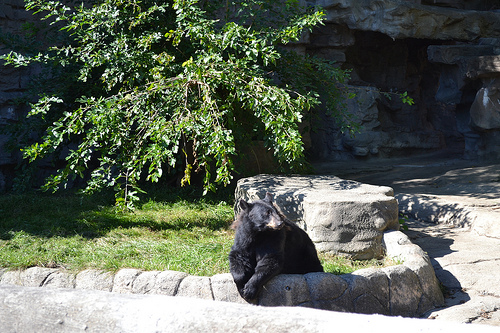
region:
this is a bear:
[226, 190, 312, 287]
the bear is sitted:
[224, 192, 314, 297]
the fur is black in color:
[292, 235, 309, 253]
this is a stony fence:
[375, 240, 425, 305]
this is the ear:
[235, 196, 249, 211]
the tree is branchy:
[116, 32, 308, 151]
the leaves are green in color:
[126, 103, 197, 142]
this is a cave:
[378, 39, 461, 136]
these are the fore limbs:
[221, 256, 278, 293]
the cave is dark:
[366, 50, 431, 91]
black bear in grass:
[232, 192, 320, 298]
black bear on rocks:
[233, 193, 323, 301]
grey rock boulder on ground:
[236, 175, 398, 253]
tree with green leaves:
[7, 0, 322, 205]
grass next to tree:
[6, 192, 234, 275]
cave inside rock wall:
[348, 25, 449, 150]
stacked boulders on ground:
[309, 6, 478, 158]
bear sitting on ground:
[233, 190, 323, 295]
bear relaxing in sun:
[233, 191, 323, 302]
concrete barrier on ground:
[3, 231, 439, 331]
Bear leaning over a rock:
[216, 199, 289, 291]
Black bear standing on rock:
[195, 160, 327, 283]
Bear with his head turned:
[191, 162, 297, 237]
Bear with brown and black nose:
[243, 208, 304, 248]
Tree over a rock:
[54, 45, 276, 192]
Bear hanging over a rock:
[211, 173, 343, 307]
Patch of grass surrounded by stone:
[58, 183, 209, 285]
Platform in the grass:
[231, 160, 428, 269]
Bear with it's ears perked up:
[214, 175, 296, 227]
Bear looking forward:
[231, 179, 308, 250]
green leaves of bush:
[5, 2, 407, 213]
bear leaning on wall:
[227, 195, 323, 300]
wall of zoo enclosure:
[1, 1, 496, 173]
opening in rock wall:
[345, 26, 463, 159]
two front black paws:
[231, 266, 285, 304]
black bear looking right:
[227, 193, 322, 303]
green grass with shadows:
[0, 181, 239, 269]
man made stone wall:
[2, 231, 440, 316]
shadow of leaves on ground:
[395, 193, 470, 235]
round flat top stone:
[233, 173, 392, 256]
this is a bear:
[226, 190, 292, 290]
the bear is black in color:
[234, 242, 285, 281]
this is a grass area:
[94, 210, 166, 245]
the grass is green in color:
[44, 213, 144, 267]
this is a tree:
[111, 21, 278, 138]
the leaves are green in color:
[163, 87, 231, 141]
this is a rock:
[320, 169, 382, 236]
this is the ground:
[440, 286, 478, 329]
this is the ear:
[231, 197, 248, 207]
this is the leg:
[252, 264, 262, 292]